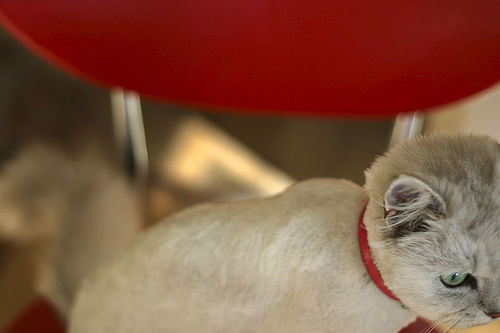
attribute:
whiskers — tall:
[417, 306, 466, 331]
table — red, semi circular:
[42, 0, 489, 131]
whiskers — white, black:
[418, 310, 491, 330]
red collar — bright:
[341, 200, 411, 305]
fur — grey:
[2, 130, 499, 332]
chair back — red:
[3, 0, 498, 80]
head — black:
[360, 131, 499, 331]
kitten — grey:
[90, 87, 499, 315]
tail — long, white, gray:
[14, 158, 134, 296]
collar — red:
[351, 209, 401, 290]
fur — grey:
[62, 122, 498, 332]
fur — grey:
[116, 198, 364, 329]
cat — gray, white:
[2, 129, 499, 331]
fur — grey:
[277, 253, 327, 295]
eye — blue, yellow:
[439, 270, 471, 285]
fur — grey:
[241, 214, 302, 296]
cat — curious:
[68, 125, 495, 331]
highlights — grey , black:
[170, 220, 467, 322]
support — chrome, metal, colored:
[113, 86, 158, 186]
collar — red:
[353, 193, 411, 309]